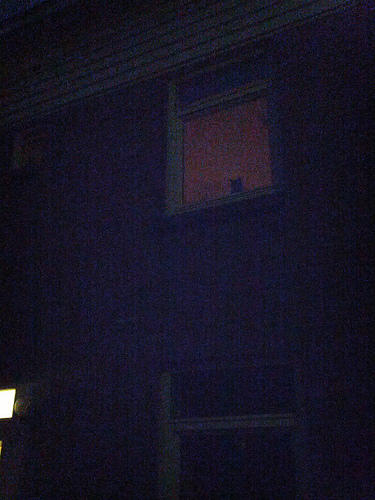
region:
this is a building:
[82, 105, 160, 359]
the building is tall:
[61, 120, 123, 469]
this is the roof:
[58, 18, 153, 66]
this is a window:
[177, 78, 275, 196]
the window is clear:
[185, 106, 266, 191]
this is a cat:
[226, 174, 244, 194]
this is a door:
[179, 437, 295, 498]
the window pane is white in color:
[172, 123, 182, 206]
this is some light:
[0, 385, 17, 416]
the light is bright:
[0, 389, 12, 419]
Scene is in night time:
[6, 2, 373, 497]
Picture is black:
[0, 2, 374, 498]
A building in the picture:
[6, 1, 372, 497]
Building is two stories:
[7, 2, 369, 494]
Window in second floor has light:
[151, 30, 293, 222]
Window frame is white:
[152, 30, 295, 225]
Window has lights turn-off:
[146, 345, 326, 497]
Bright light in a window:
[0, 378, 18, 420]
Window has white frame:
[148, 349, 324, 496]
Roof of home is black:
[0, 0, 361, 116]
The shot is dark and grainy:
[1, 0, 373, 498]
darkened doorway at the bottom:
[156, 351, 315, 497]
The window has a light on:
[157, 45, 287, 217]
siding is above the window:
[1, 0, 373, 126]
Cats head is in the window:
[225, 173, 249, 200]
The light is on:
[0, 387, 31, 418]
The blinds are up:
[167, 53, 284, 206]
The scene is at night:
[1, 0, 372, 498]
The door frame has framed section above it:
[155, 362, 314, 498]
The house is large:
[1, 0, 374, 498]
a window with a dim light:
[165, 38, 282, 223]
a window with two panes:
[161, 39, 279, 221]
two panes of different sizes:
[159, 38, 284, 228]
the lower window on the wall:
[153, 362, 314, 496]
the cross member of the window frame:
[168, 406, 302, 437]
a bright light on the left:
[0, 388, 19, 421]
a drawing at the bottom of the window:
[220, 170, 245, 197]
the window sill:
[162, 184, 292, 222]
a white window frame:
[165, 40, 285, 217]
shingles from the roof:
[0, 0, 339, 133]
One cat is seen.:
[224, 174, 247, 199]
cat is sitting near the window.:
[139, 86, 307, 226]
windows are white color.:
[149, 121, 311, 218]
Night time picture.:
[25, 30, 335, 488]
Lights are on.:
[3, 381, 36, 437]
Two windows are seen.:
[125, 72, 311, 499]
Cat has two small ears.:
[226, 173, 254, 184]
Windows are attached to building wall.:
[141, 170, 316, 254]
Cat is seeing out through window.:
[225, 170, 246, 203]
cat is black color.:
[226, 177, 246, 196]